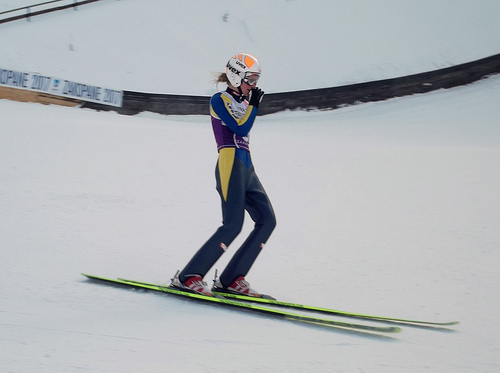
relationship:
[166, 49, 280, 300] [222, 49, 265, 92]
person wearing helmet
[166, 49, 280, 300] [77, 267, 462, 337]
person standing on skis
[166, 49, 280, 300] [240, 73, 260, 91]
person wearing goggles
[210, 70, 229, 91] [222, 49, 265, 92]
hair hanging from helmet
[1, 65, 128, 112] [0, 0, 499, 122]
sign on gate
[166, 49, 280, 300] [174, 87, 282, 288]
person wearing skiing outfit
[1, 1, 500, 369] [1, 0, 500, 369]
snow on ground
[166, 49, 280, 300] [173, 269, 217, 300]
person wearing shoe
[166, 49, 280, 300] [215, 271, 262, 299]
person wearing shoe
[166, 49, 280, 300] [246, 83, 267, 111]
person has hand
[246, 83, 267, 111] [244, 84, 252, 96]
hand in front of mouth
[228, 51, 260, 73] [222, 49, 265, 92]
shape on helmet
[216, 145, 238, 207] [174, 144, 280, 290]
triangle on pants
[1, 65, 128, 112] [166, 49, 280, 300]
sign behind person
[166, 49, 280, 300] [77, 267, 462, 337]
person wearing skis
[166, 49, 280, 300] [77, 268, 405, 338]
person wearing ski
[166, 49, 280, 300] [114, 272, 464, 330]
person wearing ski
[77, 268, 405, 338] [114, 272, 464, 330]
ski next to ski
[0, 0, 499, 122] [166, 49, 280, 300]
gate behind person